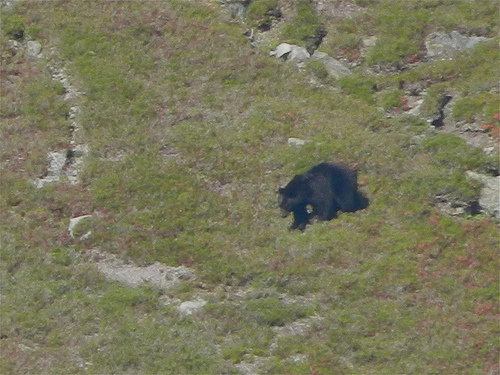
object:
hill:
[0, 2, 500, 375]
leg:
[290, 209, 309, 230]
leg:
[315, 200, 337, 221]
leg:
[337, 190, 366, 212]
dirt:
[86, 245, 220, 325]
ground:
[0, 0, 500, 375]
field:
[0, 0, 500, 375]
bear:
[274, 161, 370, 233]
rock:
[269, 39, 327, 78]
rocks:
[239, 0, 360, 81]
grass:
[0, 0, 500, 375]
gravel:
[115, 266, 180, 283]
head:
[277, 178, 310, 218]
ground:
[150, 154, 227, 235]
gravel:
[49, 136, 83, 182]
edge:
[290, 207, 373, 232]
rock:
[97, 235, 192, 308]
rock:
[50, 215, 110, 265]